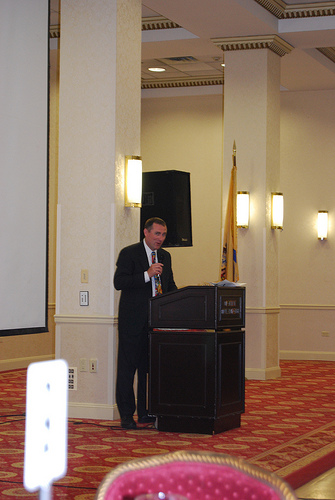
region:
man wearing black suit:
[107, 210, 182, 433]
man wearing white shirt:
[126, 230, 178, 303]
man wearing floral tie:
[142, 233, 174, 313]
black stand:
[140, 267, 271, 452]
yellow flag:
[214, 166, 247, 293]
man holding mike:
[98, 206, 186, 316]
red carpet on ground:
[0, 337, 334, 490]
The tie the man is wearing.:
[152, 252, 160, 296]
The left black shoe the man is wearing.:
[120, 416, 137, 428]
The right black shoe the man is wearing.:
[139, 412, 153, 421]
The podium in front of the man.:
[152, 282, 244, 431]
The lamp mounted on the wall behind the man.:
[125, 154, 141, 205]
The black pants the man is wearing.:
[117, 321, 145, 417]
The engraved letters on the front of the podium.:
[222, 301, 240, 314]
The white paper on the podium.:
[213, 278, 244, 287]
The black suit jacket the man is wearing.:
[113, 244, 176, 298]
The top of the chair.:
[99, 451, 296, 499]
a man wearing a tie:
[149, 247, 159, 275]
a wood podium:
[147, 276, 248, 429]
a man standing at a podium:
[115, 214, 250, 437]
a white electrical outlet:
[78, 353, 87, 375]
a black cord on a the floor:
[72, 413, 163, 439]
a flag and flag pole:
[218, 133, 240, 288]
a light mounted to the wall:
[264, 186, 286, 231]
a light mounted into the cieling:
[147, 63, 169, 74]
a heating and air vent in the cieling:
[162, 48, 200, 69]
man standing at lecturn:
[118, 218, 180, 424]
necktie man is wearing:
[150, 250, 162, 291]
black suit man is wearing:
[113, 245, 175, 423]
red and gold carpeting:
[0, 342, 333, 497]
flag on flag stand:
[222, 142, 245, 283]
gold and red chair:
[98, 453, 293, 499]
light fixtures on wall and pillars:
[120, 154, 326, 245]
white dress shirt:
[146, 243, 163, 294]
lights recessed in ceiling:
[147, 54, 224, 80]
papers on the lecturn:
[210, 276, 241, 288]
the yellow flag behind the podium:
[219, 122, 245, 283]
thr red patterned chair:
[92, 447, 295, 497]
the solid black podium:
[145, 282, 249, 436]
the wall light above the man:
[124, 154, 144, 207]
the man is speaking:
[113, 217, 179, 429]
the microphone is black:
[157, 252, 165, 263]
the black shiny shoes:
[121, 419, 136, 430]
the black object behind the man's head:
[139, 167, 193, 248]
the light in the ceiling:
[147, 67, 166, 73]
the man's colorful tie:
[151, 250, 162, 295]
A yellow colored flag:
[215, 138, 242, 283]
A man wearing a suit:
[110, 216, 178, 429]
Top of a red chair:
[93, 448, 298, 498]